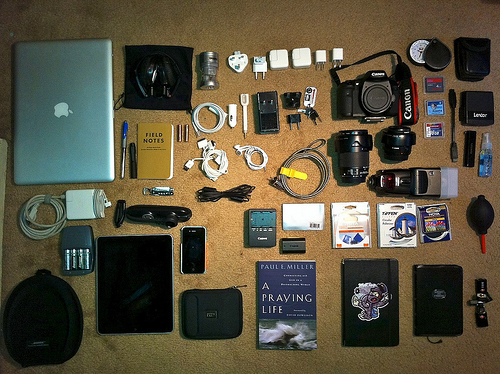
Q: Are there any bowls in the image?
A: No, there are no bowls.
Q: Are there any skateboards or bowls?
A: No, there are no bowls or skateboards.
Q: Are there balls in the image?
A: No, there are no balls.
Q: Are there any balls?
A: No, there are no balls.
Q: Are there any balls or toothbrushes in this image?
A: No, there are no balls or toothbrushes.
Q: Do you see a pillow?
A: No, there are no pillows.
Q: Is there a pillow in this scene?
A: No, there are no pillows.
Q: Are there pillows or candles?
A: No, there are no pillows or candles.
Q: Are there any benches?
A: No, there are no benches.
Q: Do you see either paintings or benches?
A: No, there are no benches or paintings.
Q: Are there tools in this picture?
A: No, there are no tools.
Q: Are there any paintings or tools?
A: No, there are no tools or paintings.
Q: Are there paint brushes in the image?
A: No, there are no paint brushes.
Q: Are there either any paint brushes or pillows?
A: No, there are no paint brushes or pillows.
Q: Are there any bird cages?
A: No, there are no bird cages.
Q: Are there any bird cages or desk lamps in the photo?
A: No, there are no bird cages or desk lamps.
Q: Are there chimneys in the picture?
A: No, there are no chimneys.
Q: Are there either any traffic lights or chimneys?
A: No, there are no chimneys or traffic lights.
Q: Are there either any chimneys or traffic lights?
A: No, there are no chimneys or traffic lights.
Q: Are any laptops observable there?
A: Yes, there is a laptop.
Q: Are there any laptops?
A: Yes, there is a laptop.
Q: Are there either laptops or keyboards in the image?
A: Yes, there is a laptop.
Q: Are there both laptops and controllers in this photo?
A: No, there is a laptop but no controllers.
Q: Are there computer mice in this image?
A: No, there are no computer mice.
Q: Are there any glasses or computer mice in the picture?
A: No, there are no computer mice or glasses.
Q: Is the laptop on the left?
A: Yes, the laptop is on the left of the image.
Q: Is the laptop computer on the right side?
A: No, the laptop computer is on the left of the image.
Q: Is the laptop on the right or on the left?
A: The laptop is on the left of the image.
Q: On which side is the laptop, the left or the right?
A: The laptop is on the left of the image.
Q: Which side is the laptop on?
A: The laptop is on the left of the image.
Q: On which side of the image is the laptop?
A: The laptop is on the left of the image.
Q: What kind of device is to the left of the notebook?
A: The device is a laptop.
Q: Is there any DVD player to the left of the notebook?
A: No, there is a laptop to the left of the notebook.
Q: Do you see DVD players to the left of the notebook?
A: No, there is a laptop to the left of the notebook.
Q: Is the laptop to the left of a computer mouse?
A: No, the laptop is to the left of the notebook.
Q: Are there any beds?
A: No, there are no beds.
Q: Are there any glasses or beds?
A: No, there are no beds or glasses.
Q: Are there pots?
A: No, there are no pots.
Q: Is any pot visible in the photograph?
A: No, there are no pots.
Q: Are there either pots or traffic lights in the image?
A: No, there are no pots or traffic lights.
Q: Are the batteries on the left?
A: Yes, the batteries are on the left of the image.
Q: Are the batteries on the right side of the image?
A: No, the batteries are on the left of the image.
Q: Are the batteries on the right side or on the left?
A: The batteries are on the left of the image.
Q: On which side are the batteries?
A: The batteries are on the left of the image.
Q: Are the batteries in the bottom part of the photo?
A: Yes, the batteries are in the bottom of the image.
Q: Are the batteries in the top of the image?
A: No, the batteries are in the bottom of the image.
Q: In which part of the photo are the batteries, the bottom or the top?
A: The batteries are in the bottom of the image.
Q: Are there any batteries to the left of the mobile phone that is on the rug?
A: Yes, there are batteries to the left of the cellphone.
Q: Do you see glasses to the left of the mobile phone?
A: No, there are batteries to the left of the mobile phone.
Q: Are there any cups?
A: No, there are no cups.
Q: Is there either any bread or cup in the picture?
A: No, there are no cups or breads.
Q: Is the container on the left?
A: Yes, the container is on the left of the image.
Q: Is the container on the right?
A: No, the container is on the left of the image.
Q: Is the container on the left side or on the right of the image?
A: The container is on the left of the image.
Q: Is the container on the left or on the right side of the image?
A: The container is on the left of the image.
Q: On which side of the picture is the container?
A: The container is on the left of the image.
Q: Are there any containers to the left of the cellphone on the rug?
A: Yes, there is a container to the left of the cell phone.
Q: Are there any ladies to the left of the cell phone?
A: No, there is a container to the left of the cell phone.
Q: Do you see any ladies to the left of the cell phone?
A: No, there is a container to the left of the cell phone.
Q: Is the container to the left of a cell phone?
A: Yes, the container is to the left of a cell phone.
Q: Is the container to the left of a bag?
A: No, the container is to the left of a cell phone.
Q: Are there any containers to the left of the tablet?
A: Yes, there is a container to the left of the tablet.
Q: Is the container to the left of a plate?
A: No, the container is to the left of the tablet.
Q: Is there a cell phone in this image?
A: Yes, there is a cell phone.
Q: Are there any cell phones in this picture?
A: Yes, there is a cell phone.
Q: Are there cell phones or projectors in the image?
A: Yes, there is a cell phone.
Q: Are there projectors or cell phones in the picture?
A: Yes, there is a cell phone.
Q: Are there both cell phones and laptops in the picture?
A: Yes, there are both a cell phone and laptops.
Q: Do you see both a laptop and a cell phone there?
A: Yes, there are both a cell phone and a laptop.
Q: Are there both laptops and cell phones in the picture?
A: Yes, there are both a cell phone and laptops.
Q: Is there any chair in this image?
A: No, there are no chairs.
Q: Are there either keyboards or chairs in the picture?
A: No, there are no chairs or keyboards.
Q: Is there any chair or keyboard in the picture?
A: No, there are no chairs or keyboards.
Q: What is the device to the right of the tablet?
A: The device is a cell phone.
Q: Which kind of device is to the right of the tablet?
A: The device is a cell phone.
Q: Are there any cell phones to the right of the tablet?
A: Yes, there is a cell phone to the right of the tablet.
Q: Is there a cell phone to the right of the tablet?
A: Yes, there is a cell phone to the right of the tablet.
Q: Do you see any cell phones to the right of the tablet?
A: Yes, there is a cell phone to the right of the tablet.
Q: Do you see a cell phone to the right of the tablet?
A: Yes, there is a cell phone to the right of the tablet.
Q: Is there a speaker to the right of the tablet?
A: No, there is a cell phone to the right of the tablet.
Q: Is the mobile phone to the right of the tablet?
A: Yes, the mobile phone is to the right of the tablet.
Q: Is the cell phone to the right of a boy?
A: No, the cell phone is to the right of the tablet.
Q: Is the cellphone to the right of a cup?
A: No, the cellphone is to the right of a battery.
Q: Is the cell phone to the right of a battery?
A: Yes, the cell phone is to the right of a battery.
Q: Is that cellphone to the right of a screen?
A: No, the cellphone is to the right of a battery.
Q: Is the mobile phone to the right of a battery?
A: Yes, the mobile phone is to the right of a battery.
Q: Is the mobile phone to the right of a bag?
A: No, the mobile phone is to the right of a battery.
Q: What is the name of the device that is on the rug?
A: The device is a cell phone.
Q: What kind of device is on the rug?
A: The device is a cell phone.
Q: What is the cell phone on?
A: The cell phone is on the rug.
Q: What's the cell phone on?
A: The cell phone is on the rug.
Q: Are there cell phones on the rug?
A: Yes, there is a cell phone on the rug.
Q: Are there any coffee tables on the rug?
A: No, there is a cell phone on the rug.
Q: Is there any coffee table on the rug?
A: No, there is a cell phone on the rug.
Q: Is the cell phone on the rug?
A: Yes, the cell phone is on the rug.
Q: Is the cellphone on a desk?
A: No, the cellphone is on the rug.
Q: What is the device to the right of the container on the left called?
A: The device is a cell phone.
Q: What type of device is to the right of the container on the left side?
A: The device is a cell phone.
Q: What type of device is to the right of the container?
A: The device is a cell phone.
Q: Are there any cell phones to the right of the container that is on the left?
A: Yes, there is a cell phone to the right of the container.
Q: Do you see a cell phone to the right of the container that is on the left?
A: Yes, there is a cell phone to the right of the container.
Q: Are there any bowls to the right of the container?
A: No, there is a cell phone to the right of the container.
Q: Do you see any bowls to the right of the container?
A: No, there is a cell phone to the right of the container.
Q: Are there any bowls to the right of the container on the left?
A: No, there is a cell phone to the right of the container.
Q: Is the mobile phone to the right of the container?
A: Yes, the mobile phone is to the right of the container.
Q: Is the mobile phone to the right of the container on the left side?
A: Yes, the mobile phone is to the right of the container.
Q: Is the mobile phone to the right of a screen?
A: No, the mobile phone is to the right of the container.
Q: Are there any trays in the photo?
A: No, there are no trays.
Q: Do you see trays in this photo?
A: No, there are no trays.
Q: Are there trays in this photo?
A: No, there are no trays.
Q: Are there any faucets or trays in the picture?
A: No, there are no trays or faucets.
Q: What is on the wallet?
A: The sticker is on the wallet.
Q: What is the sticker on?
A: The sticker is on the wallet.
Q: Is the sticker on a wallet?
A: Yes, the sticker is on a wallet.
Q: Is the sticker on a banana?
A: No, the sticker is on a wallet.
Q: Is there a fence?
A: No, there are no fences.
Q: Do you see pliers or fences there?
A: No, there are no fences or pliers.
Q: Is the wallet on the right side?
A: Yes, the wallet is on the right of the image.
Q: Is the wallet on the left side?
A: No, the wallet is on the right of the image.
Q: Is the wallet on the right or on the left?
A: The wallet is on the right of the image.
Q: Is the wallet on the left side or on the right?
A: The wallet is on the right of the image.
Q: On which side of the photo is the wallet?
A: The wallet is on the right of the image.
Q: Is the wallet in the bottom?
A: Yes, the wallet is in the bottom of the image.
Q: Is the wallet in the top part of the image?
A: No, the wallet is in the bottom of the image.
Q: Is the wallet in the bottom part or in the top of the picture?
A: The wallet is in the bottom of the image.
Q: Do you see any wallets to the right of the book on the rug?
A: Yes, there is a wallet to the right of the book.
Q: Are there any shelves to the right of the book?
A: No, there is a wallet to the right of the book.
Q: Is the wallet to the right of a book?
A: Yes, the wallet is to the right of a book.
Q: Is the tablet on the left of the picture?
A: Yes, the tablet is on the left of the image.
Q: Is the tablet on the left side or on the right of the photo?
A: The tablet is on the left of the image.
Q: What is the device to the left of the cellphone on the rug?
A: The device is a tablet.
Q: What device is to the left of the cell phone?
A: The device is a tablet.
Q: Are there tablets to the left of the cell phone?
A: Yes, there is a tablet to the left of the cell phone.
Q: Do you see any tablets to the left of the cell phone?
A: Yes, there is a tablet to the left of the cell phone.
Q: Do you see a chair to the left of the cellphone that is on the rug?
A: No, there is a tablet to the left of the cell phone.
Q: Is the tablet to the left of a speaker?
A: No, the tablet is to the left of the mobile phone.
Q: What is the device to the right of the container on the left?
A: The device is a tablet.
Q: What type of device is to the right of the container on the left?
A: The device is a tablet.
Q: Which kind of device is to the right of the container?
A: The device is a tablet.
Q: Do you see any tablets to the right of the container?
A: Yes, there is a tablet to the right of the container.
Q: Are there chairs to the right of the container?
A: No, there is a tablet to the right of the container.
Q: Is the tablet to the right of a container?
A: Yes, the tablet is to the right of a container.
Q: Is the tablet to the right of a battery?
A: Yes, the tablet is to the right of a battery.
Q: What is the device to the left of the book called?
A: The device is a tablet.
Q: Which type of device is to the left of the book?
A: The device is a tablet.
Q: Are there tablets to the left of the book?
A: Yes, there is a tablet to the left of the book.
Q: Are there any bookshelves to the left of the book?
A: No, there is a tablet to the left of the book.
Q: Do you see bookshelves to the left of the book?
A: No, there is a tablet to the left of the book.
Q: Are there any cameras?
A: Yes, there is a camera.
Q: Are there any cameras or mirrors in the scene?
A: Yes, there is a camera.